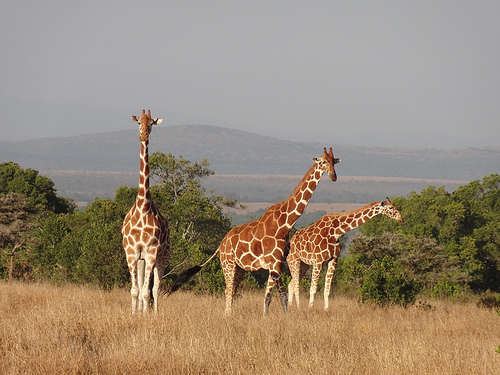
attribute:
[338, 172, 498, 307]
leaves —    tree's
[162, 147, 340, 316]
giraffe — in middle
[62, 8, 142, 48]
clouds —  white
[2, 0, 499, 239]
sky —  blue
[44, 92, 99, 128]
clouds —  white 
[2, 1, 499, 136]
sky —  blue, grey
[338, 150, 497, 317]
trees —   Tall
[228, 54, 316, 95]
clouds —  white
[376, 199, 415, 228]
giraffe head —    Giraffe's,  lowered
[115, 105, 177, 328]
giraffe — on left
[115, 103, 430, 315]
animals —  Three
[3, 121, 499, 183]
mountain —  small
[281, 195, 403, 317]
giraffe — on right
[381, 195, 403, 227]
head — facing right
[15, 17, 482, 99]
sky —  blue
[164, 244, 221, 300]
tail —  giraffe's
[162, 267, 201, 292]
tip —  Black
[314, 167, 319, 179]
spot —  Animal's,   brown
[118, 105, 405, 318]
giraffes — standing,  Three,  in wild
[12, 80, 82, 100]
clouds —  white 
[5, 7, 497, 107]
sky —  blue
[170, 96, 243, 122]
clouds —  white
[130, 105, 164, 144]
head —  giraffe's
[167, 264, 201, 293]
hair —  Black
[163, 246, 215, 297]
tail —  giraffe's